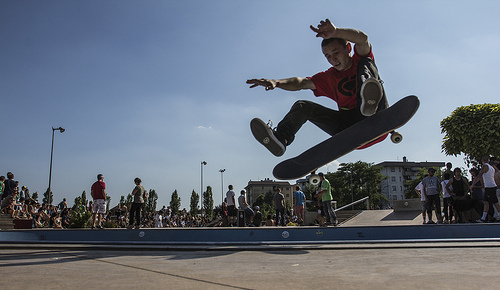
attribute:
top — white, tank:
[475, 160, 499, 192]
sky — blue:
[0, 0, 499, 213]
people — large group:
[0, 170, 340, 228]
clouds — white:
[133, 93, 272, 172]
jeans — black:
[273, 97, 390, 134]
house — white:
[370, 155, 448, 207]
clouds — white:
[172, 97, 208, 124]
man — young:
[243, 17, 399, 156]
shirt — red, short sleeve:
[271, 33, 428, 145]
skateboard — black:
[268, 91, 423, 185]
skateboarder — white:
[243, 14, 395, 159]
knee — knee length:
[88, 199, 110, 211]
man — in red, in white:
[80, 174, 125, 237]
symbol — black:
[334, 74, 354, 99]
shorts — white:
[89, 197, 107, 214]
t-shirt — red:
[301, 52, 385, 122]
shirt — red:
[306, 53, 392, 102]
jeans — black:
[269, 91, 395, 144]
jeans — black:
[276, 97, 386, 152]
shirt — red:
[304, 49, 380, 109]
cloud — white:
[141, 88, 225, 151]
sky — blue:
[10, 9, 456, 180]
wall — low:
[70, 221, 463, 250]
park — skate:
[19, 152, 480, 268]